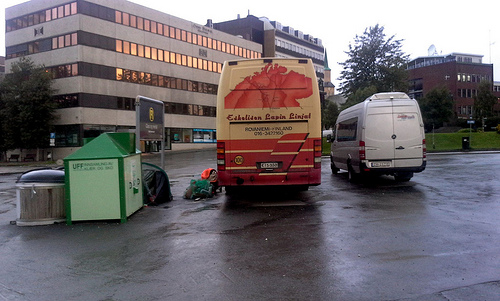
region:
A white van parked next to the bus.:
[203, 33, 455, 209]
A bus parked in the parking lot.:
[203, 54, 318, 217]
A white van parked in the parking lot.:
[330, 86, 439, 190]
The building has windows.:
[111, 9, 234, 99]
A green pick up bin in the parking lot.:
[70, 131, 143, 234]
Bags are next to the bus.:
[176, 134, 225, 208]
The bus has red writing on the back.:
[209, 102, 324, 142]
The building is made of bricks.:
[400, 45, 493, 147]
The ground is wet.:
[204, 216, 460, 287]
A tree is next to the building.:
[344, 33, 409, 105]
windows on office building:
[135, 20, 221, 69]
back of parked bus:
[219, 54, 325, 197]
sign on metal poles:
[131, 89, 178, 161]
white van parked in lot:
[327, 89, 433, 189]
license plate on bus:
[248, 154, 290, 180]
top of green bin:
[62, 125, 135, 172]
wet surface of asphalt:
[311, 215, 378, 272]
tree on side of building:
[15, 52, 77, 157]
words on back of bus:
[219, 104, 316, 144]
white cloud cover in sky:
[400, 0, 452, 34]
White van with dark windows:
[329, 95, 431, 180]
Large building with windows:
[0, 4, 265, 152]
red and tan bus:
[212, 57, 324, 204]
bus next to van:
[217, 41, 432, 230]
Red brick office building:
[397, 50, 499, 124]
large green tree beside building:
[4, 57, 60, 158]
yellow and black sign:
[129, 90, 169, 165]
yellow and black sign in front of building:
[132, 88, 173, 172]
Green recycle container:
[63, 129, 150, 219]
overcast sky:
[144, 3, 499, 48]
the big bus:
[212, 48, 328, 190]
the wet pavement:
[158, 205, 462, 297]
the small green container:
[64, 132, 142, 224]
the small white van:
[323, 85, 431, 183]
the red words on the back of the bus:
[217, 106, 310, 123]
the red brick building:
[386, 37, 496, 122]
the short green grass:
[428, 125, 497, 152]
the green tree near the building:
[5, 57, 51, 156]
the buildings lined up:
[6, 1, 341, 115]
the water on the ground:
[68, 208, 429, 291]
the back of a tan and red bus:
[211, 52, 324, 195]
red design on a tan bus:
[225, 60, 315, 111]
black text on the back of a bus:
[237, 122, 292, 132]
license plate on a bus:
[255, 160, 280, 166]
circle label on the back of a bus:
[231, 155, 241, 162]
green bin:
[62, 127, 143, 222]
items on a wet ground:
[180, 161, 220, 201]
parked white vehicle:
[326, 90, 446, 184]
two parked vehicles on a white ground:
[213, 58, 443, 204]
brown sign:
[135, 93, 171, 169]